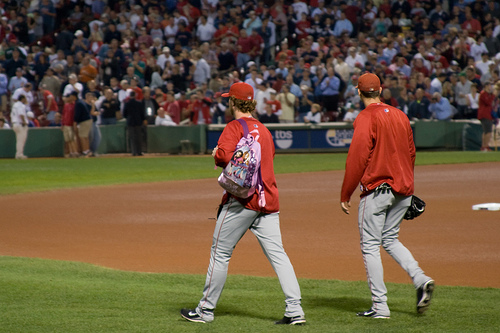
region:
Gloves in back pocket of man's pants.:
[364, 179, 400, 214]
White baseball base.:
[471, 193, 497, 220]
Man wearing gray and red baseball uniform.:
[338, 74, 436, 324]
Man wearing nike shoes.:
[359, 295, 402, 329]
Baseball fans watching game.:
[5, 0, 493, 104]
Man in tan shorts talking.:
[67, 86, 96, 155]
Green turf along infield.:
[8, 152, 202, 188]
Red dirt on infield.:
[20, 173, 208, 283]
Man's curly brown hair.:
[222, 79, 260, 114]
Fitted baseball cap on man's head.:
[356, 72, 385, 100]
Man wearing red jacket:
[336, 71, 450, 320]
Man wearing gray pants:
[178, 80, 310, 325]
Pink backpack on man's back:
[212, 118, 269, 206]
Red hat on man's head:
[352, 68, 384, 97]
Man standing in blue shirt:
[316, 66, 341, 111]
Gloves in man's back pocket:
[370, 180, 392, 210]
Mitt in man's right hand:
[402, 182, 429, 226]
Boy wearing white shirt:
[304, 101, 330, 133]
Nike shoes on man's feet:
[358, 275, 438, 331]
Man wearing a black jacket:
[121, 87, 148, 157]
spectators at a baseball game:
[4, 3, 496, 219]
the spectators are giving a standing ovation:
[13, 0, 498, 180]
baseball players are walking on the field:
[158, 56, 445, 331]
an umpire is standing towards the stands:
[118, 85, 153, 160]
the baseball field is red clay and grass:
[11, 156, 499, 328]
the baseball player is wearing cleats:
[411, 275, 438, 316]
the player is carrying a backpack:
[198, 80, 303, 331]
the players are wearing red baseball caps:
[216, 68, 380, 105]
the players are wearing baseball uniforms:
[183, 74, 438, 319]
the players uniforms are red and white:
[174, 68, 439, 328]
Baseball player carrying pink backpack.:
[179, 81, 306, 325]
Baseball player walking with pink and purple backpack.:
[178, 78, 309, 328]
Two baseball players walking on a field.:
[179, 65, 436, 329]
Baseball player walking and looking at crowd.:
[338, 69, 434, 322]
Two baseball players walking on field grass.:
[175, 74, 440, 329]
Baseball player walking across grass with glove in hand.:
[340, 66, 436, 323]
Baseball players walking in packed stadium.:
[170, 28, 437, 330]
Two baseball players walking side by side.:
[178, 70, 438, 331]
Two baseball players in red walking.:
[178, 68, 438, 332]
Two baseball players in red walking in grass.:
[170, 70, 437, 330]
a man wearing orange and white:
[331, 66, 441, 319]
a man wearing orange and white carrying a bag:
[178, 76, 309, 328]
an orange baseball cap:
[217, 80, 258, 104]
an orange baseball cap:
[356, 67, 383, 97]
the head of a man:
[219, 80, 263, 119]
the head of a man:
[353, 68, 388, 101]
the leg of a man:
[354, 206, 390, 316]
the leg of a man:
[258, 223, 306, 314]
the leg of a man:
[196, 212, 249, 309]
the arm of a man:
[336, 126, 373, 204]